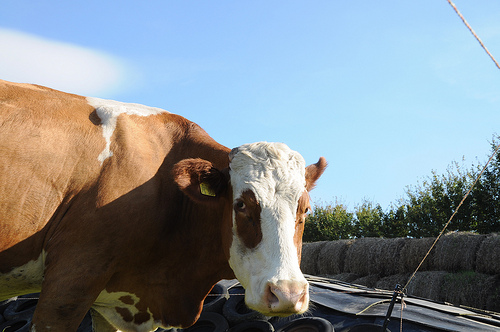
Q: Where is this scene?
A: Outside on a farm.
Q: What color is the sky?
A: Blue.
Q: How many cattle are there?
A: One.